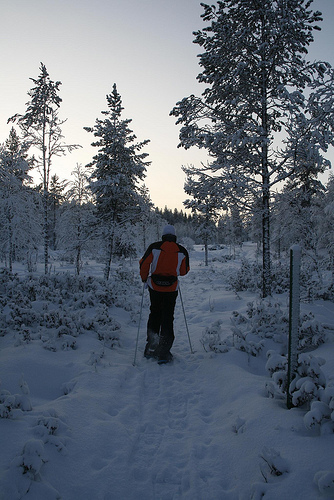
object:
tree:
[168, 0, 332, 302]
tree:
[81, 77, 151, 284]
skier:
[139, 224, 190, 365]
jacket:
[139, 240, 190, 293]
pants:
[144, 285, 179, 358]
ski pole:
[177, 281, 194, 353]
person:
[139, 224, 190, 364]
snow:
[187, 278, 207, 307]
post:
[286, 243, 301, 411]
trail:
[183, 380, 259, 500]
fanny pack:
[149, 273, 177, 287]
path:
[107, 361, 215, 449]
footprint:
[155, 395, 169, 412]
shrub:
[200, 294, 288, 366]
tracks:
[114, 282, 198, 477]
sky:
[0, 0, 192, 64]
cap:
[161, 224, 176, 236]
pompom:
[165, 236, 170, 241]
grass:
[257, 444, 283, 484]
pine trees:
[182, 182, 223, 267]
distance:
[151, 191, 193, 216]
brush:
[44, 299, 112, 343]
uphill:
[174, 301, 186, 355]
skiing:
[143, 345, 175, 364]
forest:
[0, 34, 334, 301]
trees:
[6, 60, 83, 277]